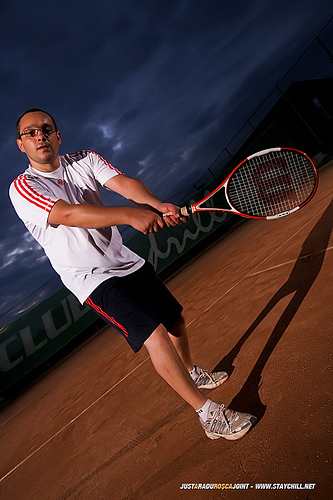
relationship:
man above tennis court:
[7, 94, 315, 443] [0, 203, 332, 496]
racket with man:
[170, 141, 316, 235] [7, 94, 315, 443]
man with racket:
[7, 94, 315, 443] [170, 141, 316, 235]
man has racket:
[7, 94, 315, 443] [170, 141, 316, 235]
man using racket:
[7, 94, 315, 443] [170, 141, 316, 235]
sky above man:
[4, 5, 307, 281] [7, 94, 315, 443]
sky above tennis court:
[4, 5, 307, 281] [0, 203, 332, 496]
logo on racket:
[247, 149, 297, 210] [159, 141, 327, 225]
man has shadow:
[7, 94, 257, 442] [219, 206, 325, 393]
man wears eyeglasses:
[7, 94, 315, 443] [17, 116, 63, 139]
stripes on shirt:
[11, 172, 55, 211] [1, 153, 146, 311]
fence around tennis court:
[187, 75, 332, 216] [11, 212, 328, 498]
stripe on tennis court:
[204, 254, 299, 303] [72, 192, 327, 477]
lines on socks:
[194, 402, 206, 417] [184, 367, 215, 423]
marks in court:
[90, 399, 168, 471] [28, 266, 311, 496]